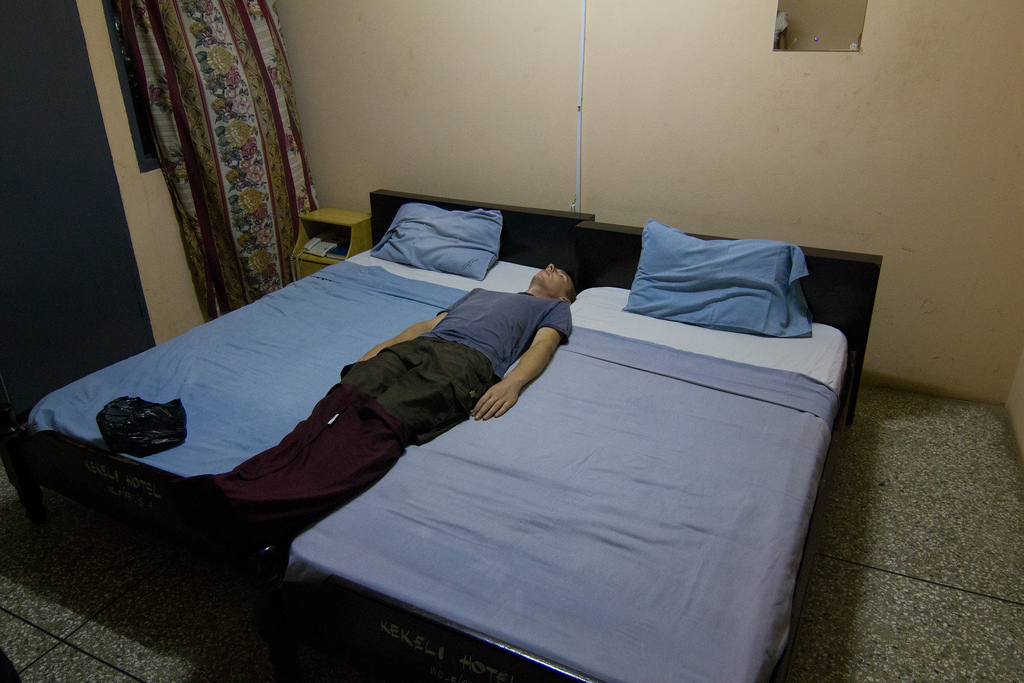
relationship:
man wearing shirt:
[183, 263, 576, 542] [420, 288, 573, 386]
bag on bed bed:
[98, 398, 191, 459] [16, 184, 877, 678]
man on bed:
[177, 261, 576, 585] [16, 184, 877, 678]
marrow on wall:
[779, 1, 874, 50] [292, 0, 1021, 409]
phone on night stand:
[301, 234, 333, 257] [290, 207, 373, 282]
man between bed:
[183, 263, 576, 542] [9, 181, 607, 675]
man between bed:
[183, 263, 576, 542] [282, 219, 902, 679]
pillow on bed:
[627, 221, 815, 343] [282, 219, 902, 679]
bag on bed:
[98, 398, 191, 459] [23, 187, 596, 592]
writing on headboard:
[70, 455, 175, 514] [0, 424, 234, 586]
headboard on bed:
[0, 424, 234, 586] [54, 190, 608, 612]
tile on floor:
[29, 642, 138, 680] [0, 368, 1022, 679]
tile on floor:
[0, 474, 182, 631] [0, 368, 1022, 679]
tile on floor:
[41, 539, 307, 679] [0, 368, 1022, 679]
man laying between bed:
[183, 263, 576, 542] [23, 187, 596, 592]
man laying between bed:
[183, 263, 576, 542] [282, 219, 902, 679]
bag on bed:
[96, 395, 187, 458] [23, 187, 596, 592]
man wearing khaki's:
[183, 263, 576, 542] [342, 338, 502, 447]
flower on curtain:
[205, 44, 243, 80] [114, 0, 331, 299]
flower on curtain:
[241, 130, 262, 144] [132, 4, 357, 322]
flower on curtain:
[245, 187, 271, 211] [107, 0, 363, 342]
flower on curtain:
[251, 204, 271, 230] [107, 0, 363, 342]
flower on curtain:
[234, 214, 273, 249] [141, 15, 310, 320]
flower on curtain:
[223, 69, 243, 123] [134, 8, 333, 320]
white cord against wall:
[554, 0, 594, 241] [292, 0, 1021, 409]